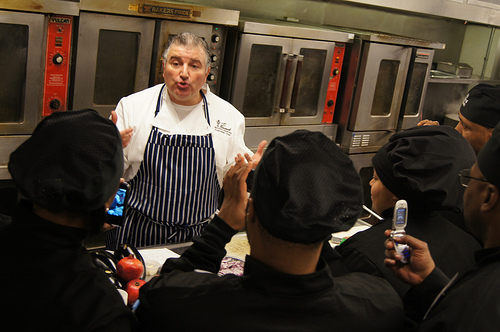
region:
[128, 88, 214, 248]
black and white striped apron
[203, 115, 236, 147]
black writing on side of shirt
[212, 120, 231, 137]
logo on side of shirt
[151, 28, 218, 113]
head of man speaking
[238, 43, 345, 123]
oven in background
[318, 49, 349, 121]
knobs on side of oven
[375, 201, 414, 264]
silver flip phone taking picture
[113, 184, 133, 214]
black phone in hand of person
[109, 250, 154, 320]
red food on a plate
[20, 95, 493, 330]
group of people watching man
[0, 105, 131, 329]
person holding cell phone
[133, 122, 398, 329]
person holding cell phone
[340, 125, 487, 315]
person holding cell phone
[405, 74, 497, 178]
person holding cell phone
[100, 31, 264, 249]
man wearing striped apron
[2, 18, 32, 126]
oven door window behind man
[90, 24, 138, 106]
oven door window behind man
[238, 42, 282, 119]
oven door window behind man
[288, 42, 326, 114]
oven door window behind man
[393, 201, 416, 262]
a cell phone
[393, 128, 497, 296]
a person holding a cell phone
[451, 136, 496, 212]
a man wearing glasses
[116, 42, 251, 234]
a man wearing a white shirt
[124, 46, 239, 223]
a man wearing a black and white apron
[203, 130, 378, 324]
a man wearing a black hat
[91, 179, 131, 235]
the screen of a camera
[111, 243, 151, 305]
two apple sitting on the counter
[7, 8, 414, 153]
metal ovens behind the man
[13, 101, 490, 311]
people dressed in black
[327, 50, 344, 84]
black control knobs on oven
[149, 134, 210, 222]
black and white stripes on apron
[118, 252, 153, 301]
two red apples sitting on table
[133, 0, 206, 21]
sign on top of silver metal oven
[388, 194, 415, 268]
small silver flip cellphone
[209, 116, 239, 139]
writing on front of white shirt of chef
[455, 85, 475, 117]
white writing on front of hat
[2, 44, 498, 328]
chef being filmed by students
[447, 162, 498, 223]
man wearing black metal eye glasses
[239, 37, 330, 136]
silver metal doors on front of oven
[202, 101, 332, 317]
this is a person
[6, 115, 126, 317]
this is a person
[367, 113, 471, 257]
this is a person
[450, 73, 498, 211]
this is a person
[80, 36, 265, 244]
this is a person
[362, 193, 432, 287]
this is a phone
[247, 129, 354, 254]
this is a black hat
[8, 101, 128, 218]
this is a black hat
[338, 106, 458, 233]
this is a black hat